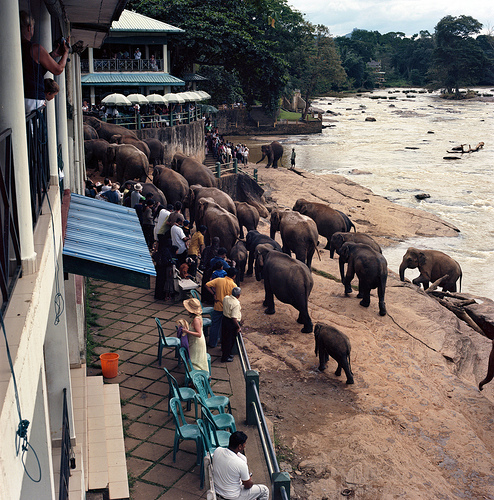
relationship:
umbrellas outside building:
[99, 90, 209, 106] [77, 6, 182, 162]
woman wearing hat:
[176, 283, 226, 376] [175, 290, 209, 320]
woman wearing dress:
[177, 298, 211, 381] [183, 312, 211, 374]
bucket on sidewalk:
[99, 344, 120, 380] [86, 278, 273, 498]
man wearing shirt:
[208, 430, 270, 499] [208, 448, 253, 498]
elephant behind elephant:
[313, 326, 353, 381] [256, 244, 311, 328]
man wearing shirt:
[204, 267, 237, 348] [204, 275, 241, 311]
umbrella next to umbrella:
[99, 90, 133, 107] [127, 92, 150, 107]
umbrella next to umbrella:
[127, 92, 150, 107] [146, 95, 168, 104]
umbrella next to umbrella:
[146, 95, 168, 104] [164, 92, 186, 103]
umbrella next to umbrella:
[164, 92, 186, 103] [179, 92, 201, 103]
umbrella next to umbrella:
[179, 92, 201, 103] [196, 88, 211, 99]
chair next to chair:
[201, 406, 232, 448] [165, 395, 203, 464]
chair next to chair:
[165, 395, 203, 464] [199, 405, 234, 447]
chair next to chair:
[199, 405, 234, 447] [198, 397, 235, 430]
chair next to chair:
[198, 397, 235, 430] [163, 366, 199, 425]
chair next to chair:
[163, 366, 199, 425] [189, 368, 230, 414]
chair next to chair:
[189, 368, 230, 414] [155, 316, 183, 364]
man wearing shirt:
[203, 267, 240, 345] [207, 276, 237, 311]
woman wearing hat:
[177, 298, 211, 381] [184, 296, 203, 314]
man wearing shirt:
[208, 430, 270, 499] [204, 437, 252, 497]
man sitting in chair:
[214, 424, 262, 498] [205, 453, 216, 498]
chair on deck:
[193, 418, 216, 479] [87, 276, 270, 498]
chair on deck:
[169, 397, 203, 466] [87, 276, 270, 498]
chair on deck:
[194, 393, 237, 433] [87, 276, 270, 498]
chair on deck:
[163, 366, 199, 425] [87, 276, 270, 498]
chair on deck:
[192, 371, 233, 431] [87, 276, 270, 498]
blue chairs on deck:
[155, 317, 182, 369] [87, 276, 270, 498]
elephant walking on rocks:
[314, 321, 355, 385] [176, 166, 492, 498]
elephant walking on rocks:
[250, 240, 313, 331] [176, 166, 492, 498]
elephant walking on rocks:
[339, 241, 390, 317] [176, 166, 492, 498]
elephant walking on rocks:
[399, 245, 462, 293] [176, 166, 492, 498]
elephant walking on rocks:
[328, 227, 384, 256] [176, 166, 492, 498]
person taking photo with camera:
[19, 12, 74, 98] [50, 37, 71, 55]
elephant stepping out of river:
[398, 244, 472, 300] [294, 77, 493, 312]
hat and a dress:
[182, 296, 198, 313] [177, 308, 212, 368]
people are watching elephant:
[85, 180, 242, 379] [314, 321, 355, 385]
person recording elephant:
[19, 10, 71, 138] [255, 138, 284, 169]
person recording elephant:
[19, 10, 71, 138] [334, 240, 387, 316]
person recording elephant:
[19, 10, 71, 138] [314, 321, 355, 385]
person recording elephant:
[19, 10, 71, 138] [232, 199, 260, 234]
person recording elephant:
[19, 10, 71, 138] [104, 141, 154, 184]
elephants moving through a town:
[81, 110, 493, 387] [0, 0, 294, 497]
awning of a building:
[63, 192, 158, 290] [1, 95, 180, 471]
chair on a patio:
[169, 397, 203, 466] [92, 285, 286, 496]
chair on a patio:
[155, 360, 194, 401] [92, 285, 286, 496]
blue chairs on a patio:
[155, 317, 182, 369] [92, 285, 286, 496]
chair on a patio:
[192, 371, 233, 431] [92, 285, 286, 496]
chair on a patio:
[194, 393, 237, 433] [92, 285, 286, 496]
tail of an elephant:
[307, 229, 323, 261] [268, 206, 324, 268]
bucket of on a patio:
[99, 352, 120, 378] [97, 302, 276, 497]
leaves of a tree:
[384, 45, 405, 62] [374, 41, 397, 81]